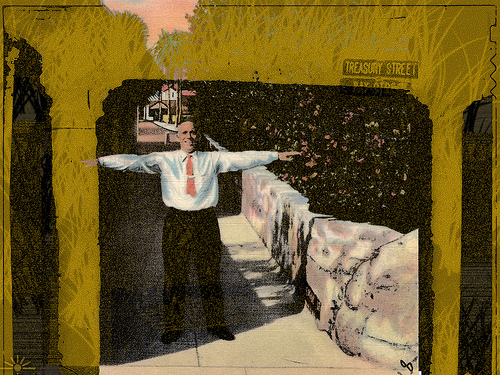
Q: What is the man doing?
A: Holding out his arms.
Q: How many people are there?
A: 1.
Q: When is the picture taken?
A: Daytime.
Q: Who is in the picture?
A: A man.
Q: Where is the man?
A: On a pathway.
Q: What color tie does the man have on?
A: Red.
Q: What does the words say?
A: Treasury Street.